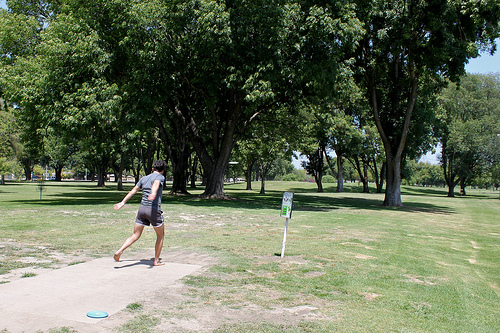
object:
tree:
[433, 86, 468, 203]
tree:
[327, 94, 357, 192]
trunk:
[383, 140, 405, 208]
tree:
[351, 0, 488, 206]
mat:
[0, 252, 203, 327]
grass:
[1, 200, 83, 248]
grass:
[296, 240, 498, 331]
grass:
[197, 263, 282, 327]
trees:
[6, 105, 47, 182]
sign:
[278, 191, 294, 220]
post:
[280, 220, 288, 256]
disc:
[83, 309, 110, 320]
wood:
[200, 163, 229, 199]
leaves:
[365, 0, 389, 17]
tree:
[145, 0, 292, 200]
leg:
[146, 217, 175, 263]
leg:
[112, 215, 145, 256]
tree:
[38, 71, 74, 182]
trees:
[235, 135, 261, 189]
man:
[111, 159, 169, 269]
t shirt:
[136, 172, 167, 205]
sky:
[471, 52, 496, 74]